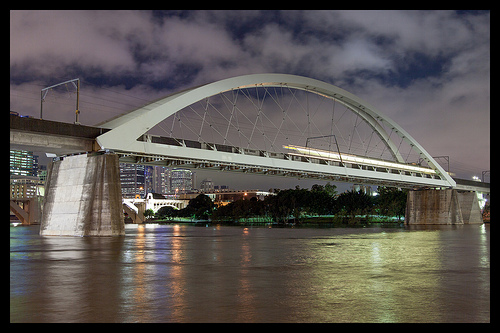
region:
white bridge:
[74, 38, 452, 222]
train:
[255, 133, 450, 184]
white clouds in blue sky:
[377, 26, 412, 47]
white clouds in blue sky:
[430, 28, 475, 72]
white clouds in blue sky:
[394, 32, 458, 79]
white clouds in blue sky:
[368, 38, 429, 68]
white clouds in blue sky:
[48, 42, 102, 76]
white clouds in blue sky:
[82, 22, 136, 66]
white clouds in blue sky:
[27, 71, 48, 83]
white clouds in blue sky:
[75, 28, 109, 86]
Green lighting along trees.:
[166, 213, 403, 224]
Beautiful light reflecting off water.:
[350, 227, 430, 284]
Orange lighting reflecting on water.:
[128, 224, 147, 248]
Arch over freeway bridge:
[112, 68, 436, 184]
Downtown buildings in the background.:
[119, 161, 197, 194]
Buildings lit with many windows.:
[11, 149, 45, 196]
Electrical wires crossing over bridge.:
[33, 83, 112, 109]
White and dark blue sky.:
[106, 30, 196, 82]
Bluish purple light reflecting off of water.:
[153, 229, 171, 263]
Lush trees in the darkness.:
[275, 183, 340, 213]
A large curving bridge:
[110, 63, 430, 194]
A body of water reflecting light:
[258, 250, 447, 312]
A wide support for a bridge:
[27, 161, 143, 241]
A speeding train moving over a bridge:
[285, 135, 429, 174]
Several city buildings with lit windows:
[122, 163, 187, 188]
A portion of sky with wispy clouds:
[82, 13, 189, 71]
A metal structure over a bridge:
[35, 76, 83, 127]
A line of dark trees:
[255, 190, 365, 220]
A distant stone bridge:
[127, 195, 185, 217]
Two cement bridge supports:
[399, 189, 487, 234]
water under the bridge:
[20, 240, 478, 324]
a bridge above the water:
[45, 91, 466, 185]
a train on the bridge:
[286, 137, 436, 173]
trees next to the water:
[177, 200, 397, 218]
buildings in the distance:
[13, 153, 179, 198]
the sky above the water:
[47, 33, 399, 128]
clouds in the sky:
[370, 74, 455, 166]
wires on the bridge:
[205, 98, 372, 153]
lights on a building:
[12, 152, 30, 168]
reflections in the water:
[135, 241, 285, 321]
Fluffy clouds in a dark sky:
[11, 12, 485, 192]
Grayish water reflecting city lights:
[14, 220, 491, 325]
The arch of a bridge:
[93, 71, 458, 191]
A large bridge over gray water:
[11, 73, 489, 240]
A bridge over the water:
[122, 190, 189, 221]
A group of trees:
[160, 190, 405, 222]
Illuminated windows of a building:
[10, 150, 37, 175]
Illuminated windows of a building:
[120, 163, 147, 195]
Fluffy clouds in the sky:
[12, 13, 487, 188]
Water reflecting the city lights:
[15, 225, 489, 324]